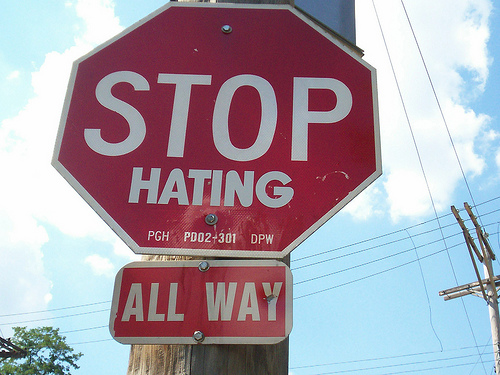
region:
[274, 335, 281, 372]
part of a pole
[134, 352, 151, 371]
part of a post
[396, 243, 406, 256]
part of a line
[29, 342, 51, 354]
part of a branch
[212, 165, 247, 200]
part of a post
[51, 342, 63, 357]
part of a branch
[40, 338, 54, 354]
side of a branch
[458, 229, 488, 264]
part of a pole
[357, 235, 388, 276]
Cables in the photo.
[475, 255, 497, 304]
Power poles in the photo.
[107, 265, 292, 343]
A signage with 'ALL WAY' writings.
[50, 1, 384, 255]
A STOP sign in the photo.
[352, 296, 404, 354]
Blue skies in the photo.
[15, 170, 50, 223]
White clouds in the photo.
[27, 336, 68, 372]
A tree in the photo.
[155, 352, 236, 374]
A wooden pole in the photo.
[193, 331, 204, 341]
A rivet in the picture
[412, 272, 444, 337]
A hanging cable in the photo.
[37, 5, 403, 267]
red and white stop sign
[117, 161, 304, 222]
white writing that isn't typically on a stop sign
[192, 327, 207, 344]
silver bolt attaching the sign to the pole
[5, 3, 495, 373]
powerlines running along the poles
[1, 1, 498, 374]
bright white clouds in the sky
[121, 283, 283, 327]
white writing on a red background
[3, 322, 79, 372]
dark green tree top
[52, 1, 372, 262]
white line outlining the sign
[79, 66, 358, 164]
white writing in all caps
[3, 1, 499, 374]
bright blue sky with clouds in it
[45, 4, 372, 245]
a stop sign on the pole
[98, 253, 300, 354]
a little sign under the stop sign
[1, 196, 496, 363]
power lines hanging from the poles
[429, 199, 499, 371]
the power pole holding all the lines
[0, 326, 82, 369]
the green leafy tree in the corner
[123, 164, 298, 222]
the extra writing on the sign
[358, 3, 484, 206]
the fluffy white cloud in the sky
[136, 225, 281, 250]
some wriing on the bottom of the sign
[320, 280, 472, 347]
a patch of blue sky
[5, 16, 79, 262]
another white fluffy cloud in the sky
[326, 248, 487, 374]
The sky is clear and blue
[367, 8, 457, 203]
The white cloud is fluffy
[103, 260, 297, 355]
The sign say's "all way"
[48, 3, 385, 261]
The stop sign is red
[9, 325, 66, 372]
The leaves on the tree is green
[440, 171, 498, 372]
The power pole is white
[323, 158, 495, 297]
The power lines are black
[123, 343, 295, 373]
The pole is made of wood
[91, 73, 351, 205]
The sign say's "Stop hating"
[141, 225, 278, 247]
The serial number to the sign